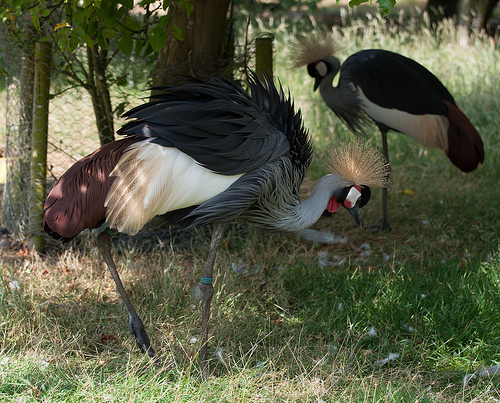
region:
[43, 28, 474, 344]
Two long legged birds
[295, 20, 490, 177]
A bird facing left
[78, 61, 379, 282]
A bird facing right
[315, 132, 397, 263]
The head of a bird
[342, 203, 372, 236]
The beak of a bird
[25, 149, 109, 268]
The tail of a bird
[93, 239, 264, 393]
The legs of a bird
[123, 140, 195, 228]
The white feathers of a bird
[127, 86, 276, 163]
The black feathers of a bird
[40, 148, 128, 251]
The red feathers of a bird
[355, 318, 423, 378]
single feathers on ground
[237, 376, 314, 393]
brown spot on the ground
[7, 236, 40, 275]
red spot on the ground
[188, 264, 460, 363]
green grass on ground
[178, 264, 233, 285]
blue band around bird's foot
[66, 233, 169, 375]
thin black and gray bird's leg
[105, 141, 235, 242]
plumed white feathers on bird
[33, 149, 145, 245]
red feathers on the bird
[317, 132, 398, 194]
tan feathers on the bird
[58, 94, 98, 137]
clear chain link fence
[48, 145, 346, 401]
bird has green band around leg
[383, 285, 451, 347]
part of some grass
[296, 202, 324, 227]
neck of a bird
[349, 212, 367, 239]
beak of a bir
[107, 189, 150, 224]
part of a bird's feather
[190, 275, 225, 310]
knee of a bird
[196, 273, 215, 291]
part of a green thing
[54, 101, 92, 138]
part of a meshed fence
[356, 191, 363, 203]
right eye of a bird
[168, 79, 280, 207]
part of a wing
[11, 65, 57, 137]
part of a stem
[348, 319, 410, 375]
white feathers on the ground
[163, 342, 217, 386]
blades of green grass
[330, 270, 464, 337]
area of green grass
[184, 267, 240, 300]
green band on the bird's leg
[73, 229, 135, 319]
long gray thin leg on bird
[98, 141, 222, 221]
large white feather on bird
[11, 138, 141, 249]
cranberry feathers on the bird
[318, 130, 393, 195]
large tan comb on bird's head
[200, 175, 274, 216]
gray feathers on front of bird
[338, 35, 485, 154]
solid black and white feathers on the bird